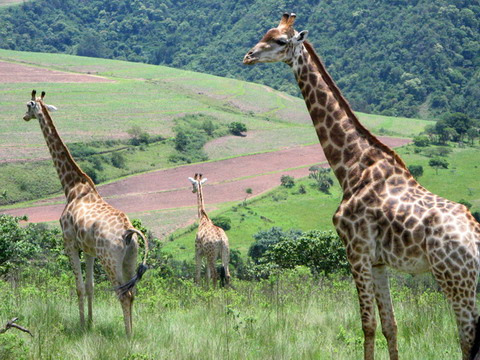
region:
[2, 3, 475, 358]
three giraffes in an open field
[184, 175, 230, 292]
a small giraffe facing away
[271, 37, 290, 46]
a giraffe's right eye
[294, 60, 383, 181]
the long neck of a giraffe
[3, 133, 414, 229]
a dirt path in a field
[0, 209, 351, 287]
short green shrubbery in a field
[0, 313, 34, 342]
a brown fallen twig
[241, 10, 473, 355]
closest giraffe is tall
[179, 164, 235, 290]
furthest giraffe looking down on field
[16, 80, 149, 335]
tall giraffe standing in grass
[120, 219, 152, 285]
brown tail with puff of black hair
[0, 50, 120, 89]
dirt area on top of green hill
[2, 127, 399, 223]
large empty dirt field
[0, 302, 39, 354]
bare dead branch is brown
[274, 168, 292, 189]
short round green bush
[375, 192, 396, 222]
unique shaped brown spot on giraffe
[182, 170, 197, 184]
left horn on head of giraffe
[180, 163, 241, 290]
a giraffe looking down a cliff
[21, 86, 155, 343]
giraffe looking across the grass landscape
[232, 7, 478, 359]
a large giraffe gazing at their companions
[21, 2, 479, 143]
an expansive dark forest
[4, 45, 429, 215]
an open grassy plain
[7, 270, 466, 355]
a grassy savannah with giraffes in it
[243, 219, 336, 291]
shrubbery in a big grassland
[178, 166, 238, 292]
a girafe grazing in a meadow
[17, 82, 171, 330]
a mammal with a long neck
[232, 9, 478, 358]
a giraffe standing in a peaceful valley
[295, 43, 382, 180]
the giraffe has a long neck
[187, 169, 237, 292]
the giraffe is facing away from the camera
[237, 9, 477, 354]
the giraffe is very tall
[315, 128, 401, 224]
the giraffe has many spots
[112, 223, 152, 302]
the giraffe is swinging its tail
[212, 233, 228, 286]
the giraffe has a long tail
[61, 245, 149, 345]
the giraffe has four legs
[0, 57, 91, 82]
the field is brown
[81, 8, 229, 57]
green trees in the forest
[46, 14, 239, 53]
large mountain area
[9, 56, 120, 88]
cleared area in the field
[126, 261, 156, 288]
long tail on the giraffe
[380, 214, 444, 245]
brown and white stripes on giraffe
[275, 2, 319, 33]
horns on top of giraffe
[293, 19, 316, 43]
ears on tall giraffe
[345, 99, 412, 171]
comb down the back of giraffe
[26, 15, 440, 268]
giraffes standing in the field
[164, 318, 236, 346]
tall grass in the field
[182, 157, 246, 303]
This is a giraffe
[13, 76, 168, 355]
This is a giraffe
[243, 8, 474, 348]
This is a giraffe